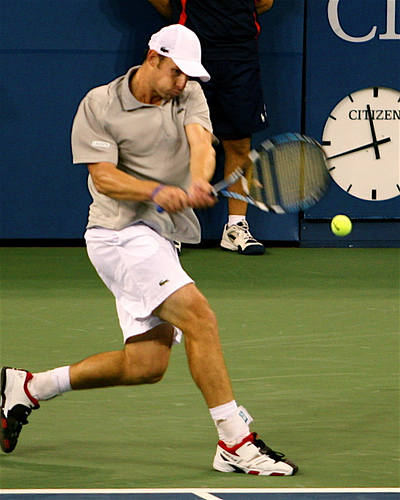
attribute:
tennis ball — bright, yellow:
[320, 201, 362, 247]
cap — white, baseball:
[146, 22, 211, 83]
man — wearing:
[11, 16, 296, 483]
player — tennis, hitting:
[0, 14, 301, 475]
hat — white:
[148, 19, 214, 83]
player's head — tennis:
[139, 22, 202, 103]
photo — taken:
[1, 0, 399, 499]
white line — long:
[0, 483, 397, 498]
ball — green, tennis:
[320, 186, 364, 258]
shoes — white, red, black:
[205, 426, 300, 478]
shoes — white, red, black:
[0, 362, 45, 454]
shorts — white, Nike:
[83, 220, 195, 336]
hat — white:
[137, 19, 239, 79]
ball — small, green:
[325, 207, 356, 243]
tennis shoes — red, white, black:
[1, 363, 305, 482]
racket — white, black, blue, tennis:
[157, 132, 330, 214]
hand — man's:
[185, 179, 217, 207]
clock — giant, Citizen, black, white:
[320, 83, 399, 205]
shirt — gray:
[68, 68, 218, 252]